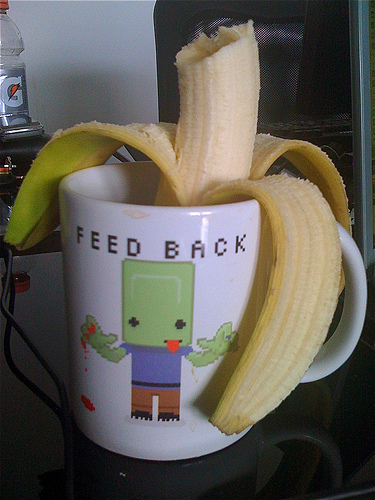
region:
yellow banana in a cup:
[143, 6, 282, 114]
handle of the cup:
[299, 219, 368, 381]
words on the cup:
[64, 226, 255, 271]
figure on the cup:
[62, 261, 244, 442]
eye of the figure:
[170, 313, 193, 338]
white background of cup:
[77, 274, 112, 305]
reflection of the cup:
[272, 407, 344, 479]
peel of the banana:
[254, 207, 357, 333]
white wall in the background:
[60, 37, 98, 83]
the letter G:
[3, 65, 29, 110]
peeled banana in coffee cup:
[3, 17, 370, 465]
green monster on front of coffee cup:
[77, 244, 245, 437]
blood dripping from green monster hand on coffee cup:
[75, 313, 121, 419]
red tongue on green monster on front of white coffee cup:
[156, 331, 185, 356]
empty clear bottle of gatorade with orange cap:
[1, 1, 38, 127]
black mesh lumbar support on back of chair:
[177, 11, 363, 135]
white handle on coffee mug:
[274, 204, 373, 401]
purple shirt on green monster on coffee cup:
[119, 340, 194, 393]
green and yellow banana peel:
[2, 114, 183, 252]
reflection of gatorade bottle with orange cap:
[1, 188, 43, 303]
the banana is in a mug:
[18, 0, 343, 475]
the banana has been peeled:
[20, 17, 368, 351]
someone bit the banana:
[167, 7, 282, 118]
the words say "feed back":
[64, 210, 253, 260]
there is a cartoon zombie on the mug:
[69, 213, 226, 445]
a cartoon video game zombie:
[68, 216, 254, 445]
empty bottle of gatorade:
[1, 1, 39, 117]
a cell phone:
[5, 106, 56, 142]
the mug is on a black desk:
[16, 46, 373, 487]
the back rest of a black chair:
[149, 6, 374, 201]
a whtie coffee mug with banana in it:
[5, 16, 363, 465]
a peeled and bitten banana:
[6, 21, 351, 437]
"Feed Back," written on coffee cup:
[72, 222, 246, 256]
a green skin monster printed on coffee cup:
[72, 257, 243, 422]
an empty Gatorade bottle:
[0, 2, 26, 133]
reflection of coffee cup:
[127, 427, 339, 498]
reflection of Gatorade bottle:
[3, 245, 39, 292]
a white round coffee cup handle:
[297, 204, 369, 388]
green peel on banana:
[3, 187, 54, 247]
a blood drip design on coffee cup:
[70, 340, 97, 412]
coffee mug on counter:
[52, 201, 332, 475]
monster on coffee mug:
[95, 263, 212, 433]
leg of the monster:
[155, 397, 185, 428]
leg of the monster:
[124, 396, 157, 425]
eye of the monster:
[124, 313, 144, 332]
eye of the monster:
[172, 316, 187, 334]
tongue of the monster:
[163, 339, 181, 356]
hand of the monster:
[193, 319, 238, 362]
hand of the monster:
[72, 318, 119, 367]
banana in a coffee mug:
[172, 38, 298, 233]